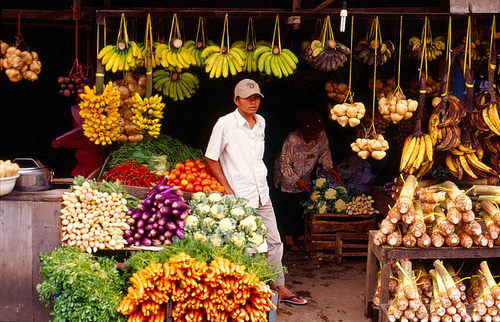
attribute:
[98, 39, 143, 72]
bananas — bunch, white, hanging, yellow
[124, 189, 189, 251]
eggplant — pile, purple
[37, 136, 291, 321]
produce — green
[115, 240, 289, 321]
carrots — pile, orange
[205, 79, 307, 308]
man — standing, light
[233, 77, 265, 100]
cap — brown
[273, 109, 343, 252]
woman — standing, looking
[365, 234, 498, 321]
stand — wooden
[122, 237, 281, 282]
tops — green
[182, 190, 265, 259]
cabbage — white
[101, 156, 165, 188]
peppers — red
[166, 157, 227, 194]
tomatoes — red, pile, these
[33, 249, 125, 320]
lettuce — green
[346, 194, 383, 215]
leeks — white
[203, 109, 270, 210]
shirt — white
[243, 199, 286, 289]
pants — grey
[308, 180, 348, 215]
cauliflower — pile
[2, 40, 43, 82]
garlic — hanging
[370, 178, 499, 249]
turnips — pile